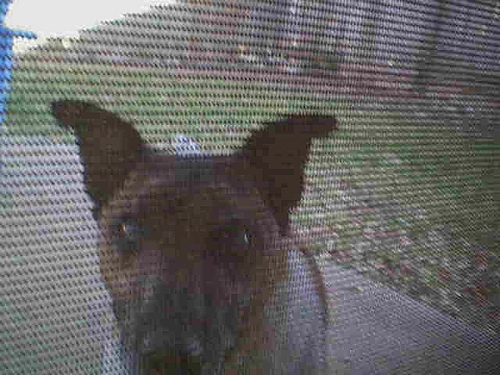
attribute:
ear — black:
[230, 111, 350, 231]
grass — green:
[5, 63, 497, 332]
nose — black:
[133, 327, 199, 370]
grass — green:
[367, 104, 495, 215]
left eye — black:
[223, 227, 251, 262]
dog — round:
[53, 102, 319, 373]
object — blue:
[2, 0, 40, 119]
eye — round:
[223, 223, 254, 259]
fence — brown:
[0, 2, 497, 374]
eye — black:
[97, 208, 154, 256]